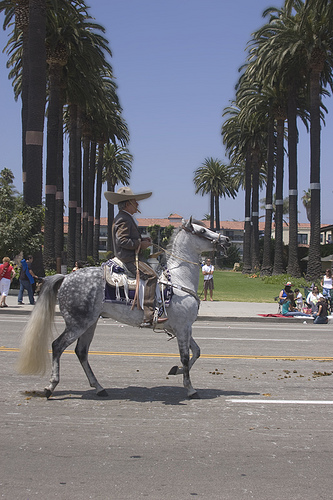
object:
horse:
[16, 214, 229, 400]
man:
[111, 180, 163, 326]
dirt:
[203, 363, 333, 389]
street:
[0, 314, 333, 500]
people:
[201, 257, 215, 303]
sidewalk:
[0, 293, 333, 325]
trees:
[192, 157, 239, 233]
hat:
[103, 186, 153, 206]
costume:
[112, 210, 158, 321]